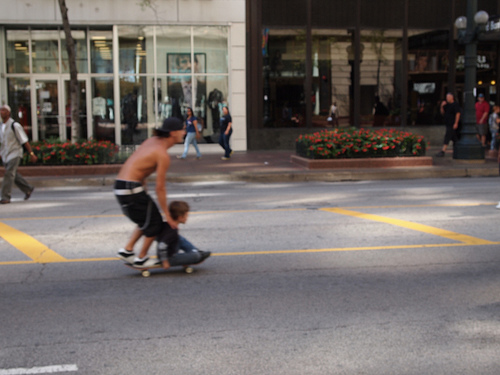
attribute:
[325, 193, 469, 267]
markings — orange